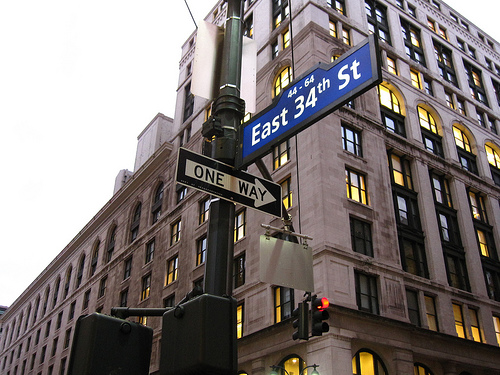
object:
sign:
[250, 60, 362, 147]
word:
[250, 107, 289, 148]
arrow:
[183, 157, 278, 208]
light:
[312, 297, 331, 312]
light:
[291, 357, 301, 364]